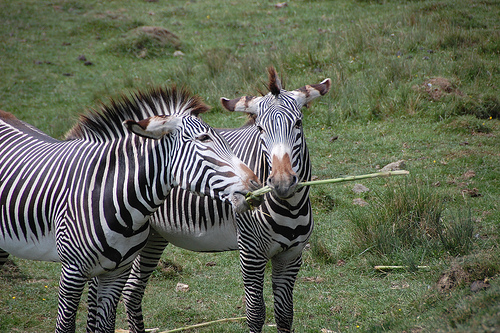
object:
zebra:
[0, 87, 263, 332]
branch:
[245, 160, 410, 200]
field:
[1, 0, 498, 333]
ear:
[123, 115, 171, 140]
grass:
[333, 38, 410, 116]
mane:
[64, 87, 211, 140]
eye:
[198, 135, 212, 142]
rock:
[110, 25, 189, 58]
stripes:
[2, 113, 63, 144]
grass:
[2, 306, 56, 330]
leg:
[54, 252, 97, 333]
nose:
[237, 162, 263, 189]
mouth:
[233, 190, 262, 210]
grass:
[348, 177, 473, 257]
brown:
[244, 166, 250, 172]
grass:
[105, 40, 179, 67]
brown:
[143, 119, 148, 127]